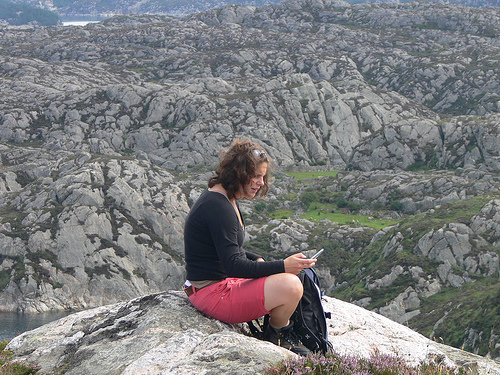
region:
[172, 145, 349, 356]
a lady on top of a mountain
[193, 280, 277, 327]
woman wearing a pair of pink shorts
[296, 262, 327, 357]
a black bag on the ground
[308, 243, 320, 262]
a cell phone in persoons hand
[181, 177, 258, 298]
the woman is wearing a black shirt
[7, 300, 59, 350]
lake in between the rocks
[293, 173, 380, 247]
green grass by the mountains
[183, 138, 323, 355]
Woman holding a cell phone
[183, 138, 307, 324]
Woman in a black shirt wearing coral shorts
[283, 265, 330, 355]
Black backpack on the ground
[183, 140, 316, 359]
Woman sitting on the ground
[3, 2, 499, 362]
Rocky hillside behind the woman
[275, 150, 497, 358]
Green foliage in the rocky hillside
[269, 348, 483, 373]
Purple flowers next to rock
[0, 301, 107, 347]
Water next to rocky hillside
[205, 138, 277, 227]
Woman with sunglasses on her head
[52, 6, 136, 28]
Water next to the rocky hillside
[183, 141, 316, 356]
A brown haired woman sitting on a rock in pink shorts.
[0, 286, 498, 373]
A white and grey rock a woman is sitting on.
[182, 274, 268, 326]
A pink pair of shorts.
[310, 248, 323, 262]
A grey phone a woman is holding.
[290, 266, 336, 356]
A black backpack in front of a woman.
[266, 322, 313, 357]
A woman's right brown boot.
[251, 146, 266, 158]
Pair of glasses on a woman's head.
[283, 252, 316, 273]
A woman's right hand.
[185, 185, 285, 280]
A long sleeve black shirt.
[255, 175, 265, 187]
Nose on a woman's face.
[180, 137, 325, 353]
woman checking her electronic device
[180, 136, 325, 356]
Woman sitting on mountain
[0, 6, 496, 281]
a mountainous landscape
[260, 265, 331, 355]
a black backpack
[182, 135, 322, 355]
woman wearing red shorts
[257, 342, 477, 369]
a patch of mountain wildflowers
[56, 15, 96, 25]
a distant body of water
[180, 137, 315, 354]
woman wearing a black shirt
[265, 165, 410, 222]
a grassy area among the rocks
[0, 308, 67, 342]
a nearby body of water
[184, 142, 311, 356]
Woman in pink shorts sitting on a rock.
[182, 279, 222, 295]
Brown belt on a waist.